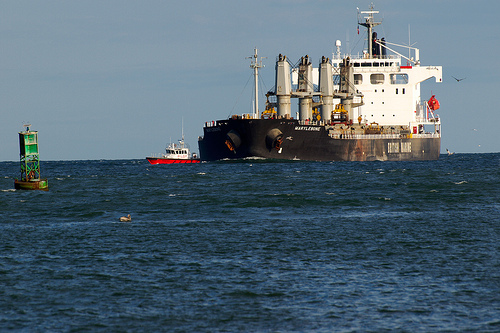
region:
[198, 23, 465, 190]
oil tanker anchored in ocean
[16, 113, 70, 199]
green buoy floating in ocean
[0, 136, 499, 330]
ocean waters are slightly choppy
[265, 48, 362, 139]
grey stacks on tanker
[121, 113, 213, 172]
red and white tugboat on ocean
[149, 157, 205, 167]
bottom of boat is red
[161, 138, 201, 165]
white top of boat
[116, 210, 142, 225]
bird resting on ocean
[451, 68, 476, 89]
bird flying next to tanker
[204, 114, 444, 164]
bottom of tanker is black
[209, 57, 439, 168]
this is a ship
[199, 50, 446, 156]
the ship is big in size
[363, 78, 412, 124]
the ship is white in color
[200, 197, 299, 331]
this is the sea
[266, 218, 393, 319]
the water is calm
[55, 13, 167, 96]
this is the sky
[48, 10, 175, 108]
the sky is grey in color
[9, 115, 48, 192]
this is a boat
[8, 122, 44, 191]
the boat is green in color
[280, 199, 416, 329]
the water is blue in color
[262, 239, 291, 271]
part of a water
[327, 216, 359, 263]
part of a water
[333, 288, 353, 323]
part of a water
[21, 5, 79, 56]
this is the sky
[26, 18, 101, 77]
the sky is blue in color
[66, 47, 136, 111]
the sky has clouds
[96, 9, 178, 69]
the clouds are white in color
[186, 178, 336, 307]
this is the water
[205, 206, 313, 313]
the water has ripples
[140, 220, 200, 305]
the water is blue in color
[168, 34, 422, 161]
the ship is big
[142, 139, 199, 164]
the boat is small